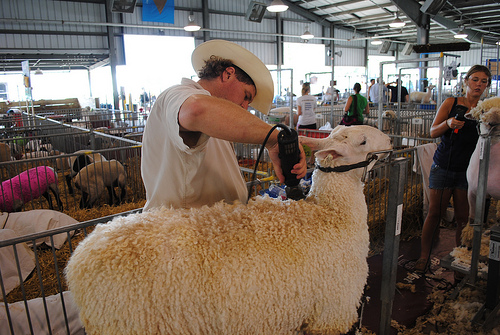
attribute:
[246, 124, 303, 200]
electric shears — black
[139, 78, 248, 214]
shirt — white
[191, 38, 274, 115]
hat — white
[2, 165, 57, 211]
blanket — pink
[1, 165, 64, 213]
sheep — white, being sheared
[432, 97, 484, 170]
tank top — blue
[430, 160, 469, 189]
shorts — jeans, blue, blue jean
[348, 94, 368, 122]
shirt — green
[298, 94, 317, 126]
shirt — white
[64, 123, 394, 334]
sheep — standing, white, large, being sheared, brown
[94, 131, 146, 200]
gate — metal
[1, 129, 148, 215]
holding pen — steel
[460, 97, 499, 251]
sheep — shaved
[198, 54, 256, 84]
hair — brown